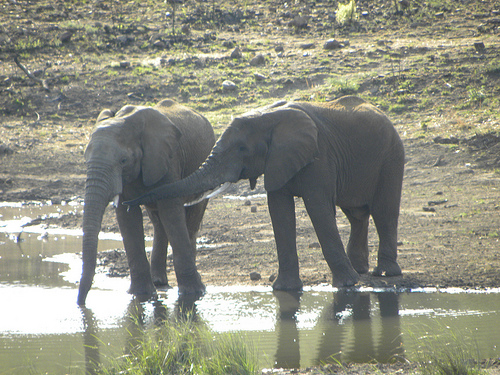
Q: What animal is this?
A: Elephant.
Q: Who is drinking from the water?
A: Elephants.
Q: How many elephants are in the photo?
A: Two.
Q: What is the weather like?
A: Sunshine.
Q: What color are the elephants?
A: Grey.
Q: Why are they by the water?
A: Drinking.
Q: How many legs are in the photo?
A: Eight.